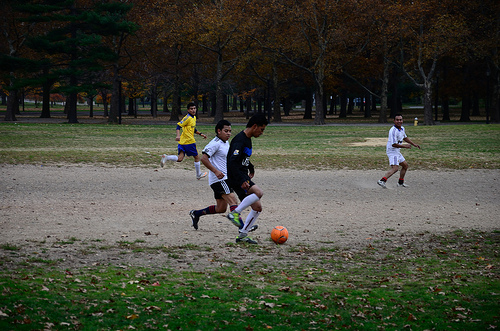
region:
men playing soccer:
[153, 84, 413, 229]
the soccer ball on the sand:
[268, 215, 297, 245]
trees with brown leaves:
[29, 9, 499, 90]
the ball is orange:
[270, 215, 296, 245]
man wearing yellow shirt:
[170, 115, 208, 140]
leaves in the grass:
[104, 260, 497, 326]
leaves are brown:
[135, 241, 433, 329]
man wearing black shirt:
[222, 133, 253, 175]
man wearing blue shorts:
[170, 138, 197, 153]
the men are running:
[167, 96, 434, 255]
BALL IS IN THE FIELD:
[272, 225, 294, 240]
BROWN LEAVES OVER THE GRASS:
[251, 284, 273, 306]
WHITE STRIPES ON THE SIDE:
[215, 178, 234, 195]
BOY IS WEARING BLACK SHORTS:
[212, 187, 219, 199]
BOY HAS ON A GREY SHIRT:
[218, 149, 226, 161]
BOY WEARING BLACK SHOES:
[192, 206, 197, 226]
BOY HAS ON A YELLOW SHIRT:
[180, 128, 195, 137]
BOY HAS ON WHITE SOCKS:
[169, 153, 174, 162]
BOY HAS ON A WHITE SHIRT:
[387, 138, 394, 153]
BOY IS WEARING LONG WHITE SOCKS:
[239, 196, 261, 208]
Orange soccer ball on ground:
[270, 225, 290, 243]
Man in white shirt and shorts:
[378, 113, 420, 190]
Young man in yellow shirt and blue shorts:
[162, 100, 208, 177]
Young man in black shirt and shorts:
[229, 110, 267, 245]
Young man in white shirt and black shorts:
[191, 118, 232, 230]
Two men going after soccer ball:
[191, 112, 291, 244]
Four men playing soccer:
[157, 97, 419, 246]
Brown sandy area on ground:
[1, 165, 498, 241]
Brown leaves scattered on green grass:
[0, 248, 496, 330]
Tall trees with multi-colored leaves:
[0, 0, 499, 122]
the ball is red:
[271, 225, 296, 238]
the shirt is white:
[200, 139, 225, 188]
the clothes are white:
[378, 124, 406, 161]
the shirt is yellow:
[178, 118, 195, 145]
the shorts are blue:
[174, 140, 199, 159]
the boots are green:
[226, 211, 255, 249]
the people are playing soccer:
[163, 96, 424, 236]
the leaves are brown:
[176, 22, 366, 58]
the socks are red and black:
[379, 173, 409, 186]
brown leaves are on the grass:
[222, 271, 359, 323]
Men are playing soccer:
[155, 98, 427, 250]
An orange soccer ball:
[264, 218, 295, 251]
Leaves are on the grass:
[2, 237, 498, 328]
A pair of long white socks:
[233, 189, 261, 242]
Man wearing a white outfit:
[375, 109, 427, 194]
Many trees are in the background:
[2, 1, 498, 129]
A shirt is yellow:
[174, 113, 199, 147]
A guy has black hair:
[241, 110, 271, 142]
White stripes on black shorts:
[206, 174, 237, 201]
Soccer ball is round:
[265, 219, 294, 248]